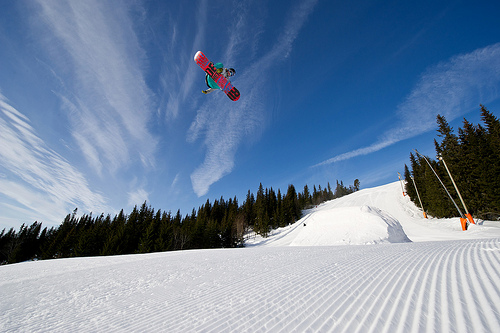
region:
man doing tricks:
[184, 47, 244, 112]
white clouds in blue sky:
[20, 17, 51, 54]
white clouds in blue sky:
[307, 110, 334, 145]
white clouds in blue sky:
[398, 39, 468, 94]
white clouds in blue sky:
[157, 112, 212, 152]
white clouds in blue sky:
[282, 45, 324, 102]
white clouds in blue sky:
[67, 111, 116, 138]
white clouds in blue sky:
[139, 150, 167, 165]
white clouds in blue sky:
[34, 62, 81, 100]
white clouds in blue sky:
[41, 128, 84, 153]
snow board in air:
[181, 18, 256, 113]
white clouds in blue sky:
[50, 55, 85, 80]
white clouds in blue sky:
[342, 93, 354, 110]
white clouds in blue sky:
[305, 126, 326, 146]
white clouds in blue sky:
[71, 156, 122, 187]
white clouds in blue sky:
[168, 132, 238, 187]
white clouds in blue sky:
[82, 55, 130, 96]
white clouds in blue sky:
[24, 46, 82, 83]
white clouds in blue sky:
[332, 73, 377, 118]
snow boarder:
[182, 38, 264, 117]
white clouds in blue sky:
[300, 103, 335, 128]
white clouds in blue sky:
[191, 118, 238, 152]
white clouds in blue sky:
[94, 172, 141, 199]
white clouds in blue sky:
[46, 21, 129, 100]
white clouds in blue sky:
[29, 150, 88, 181]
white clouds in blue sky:
[82, 38, 162, 111]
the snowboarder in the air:
[186, 33, 254, 110]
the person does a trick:
[188, 43, 255, 120]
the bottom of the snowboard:
[193, 47, 244, 104]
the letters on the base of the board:
[192, 50, 238, 102]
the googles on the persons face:
[225, 66, 238, 79]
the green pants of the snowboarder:
[206, 72, 220, 93]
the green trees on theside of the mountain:
[1, 180, 298, 275]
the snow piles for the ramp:
[293, 177, 408, 249]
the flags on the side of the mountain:
[391, 151, 477, 231]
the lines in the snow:
[218, 255, 496, 330]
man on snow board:
[174, 35, 250, 113]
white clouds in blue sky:
[9, 22, 64, 77]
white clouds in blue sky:
[44, 88, 97, 141]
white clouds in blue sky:
[198, 128, 234, 158]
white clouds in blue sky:
[60, 21, 128, 66]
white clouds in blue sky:
[61, 33, 116, 88]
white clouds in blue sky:
[159, 128, 191, 154]